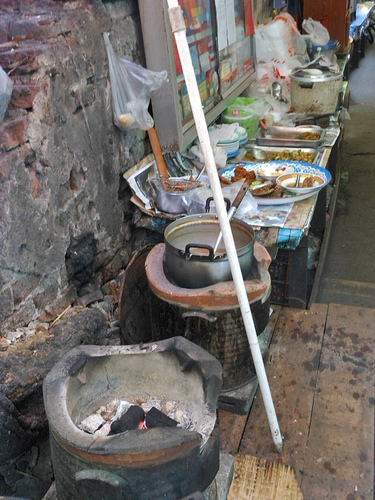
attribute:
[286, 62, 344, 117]
pot — large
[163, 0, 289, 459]
pole — long, white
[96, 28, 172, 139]
plastic bag — hanging, clear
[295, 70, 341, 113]
pot — large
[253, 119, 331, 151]
pan — square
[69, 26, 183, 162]
bag — hanging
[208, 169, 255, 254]
spoon — long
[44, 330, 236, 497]
fireplace — dented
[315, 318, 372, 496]
wood — wood grain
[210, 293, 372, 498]
planks — wooden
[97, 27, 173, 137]
bag — hanging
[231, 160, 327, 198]
bowl — large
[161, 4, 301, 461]
stick — white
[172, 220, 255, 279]
pot — silver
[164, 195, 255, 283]
pot — silver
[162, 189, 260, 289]
pot — round